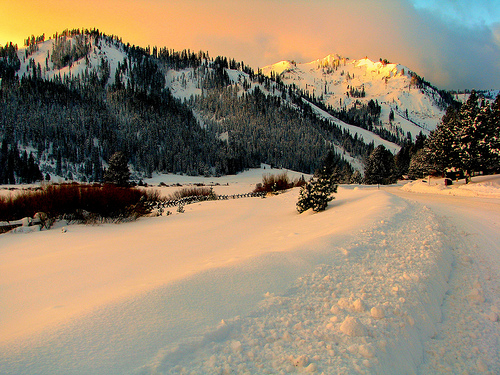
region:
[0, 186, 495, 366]
Snow is covering the ground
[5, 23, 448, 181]
Mountains are in the background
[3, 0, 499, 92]
The sky is cloudy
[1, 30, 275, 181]
The mountain is covered in trees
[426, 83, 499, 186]
Pine trees are in the background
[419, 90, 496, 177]
Pinetrees are snow covered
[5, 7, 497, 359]
Photo was taken in the daytime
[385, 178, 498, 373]
A pathway is in the snow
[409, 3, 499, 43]
A break in the clouds revealing the sky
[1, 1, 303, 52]
Clouds are orange in color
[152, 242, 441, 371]
this is the ground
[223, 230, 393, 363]
the ground is full of snow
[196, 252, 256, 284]
this is the snow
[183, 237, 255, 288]
the snow is white in color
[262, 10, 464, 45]
this is the sky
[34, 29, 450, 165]
these are the hills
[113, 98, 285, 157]
these are some trees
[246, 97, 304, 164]
the trees are tall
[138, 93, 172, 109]
the leaves are green in color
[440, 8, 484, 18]
the sky is blue in color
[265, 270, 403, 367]
The snow is white.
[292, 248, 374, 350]
The snow is white.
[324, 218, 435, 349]
The snow is white.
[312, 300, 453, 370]
The snow is white.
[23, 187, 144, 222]
the brush in the mountains is colored brown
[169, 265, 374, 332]
the snow on th eground is colored white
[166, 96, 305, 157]
the tree's are colored green in the mountains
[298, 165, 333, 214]
a few shrubs stand in a bunch on the ground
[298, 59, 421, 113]
the mountains are covered with white snow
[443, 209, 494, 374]
the snow on the ground has been driven on their is a path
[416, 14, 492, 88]
the sky above is gray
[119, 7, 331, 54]
the sun may or may not be coming up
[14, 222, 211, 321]
the snow is bright white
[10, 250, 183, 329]
the snow is colored white and has not been stepped on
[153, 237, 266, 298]
the snow is white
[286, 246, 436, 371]
the snow is not smooth here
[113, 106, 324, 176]
the mountain is covered in evergreen trees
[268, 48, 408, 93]
the sun is reflecting off the mountain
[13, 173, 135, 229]
the water appears to be red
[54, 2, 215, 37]
the sky is very pretty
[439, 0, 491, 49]
the clouds is grey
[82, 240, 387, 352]
the snow is drifted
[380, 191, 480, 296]
a path has been plowed for the road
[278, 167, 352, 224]
a lone tree stands in the picture